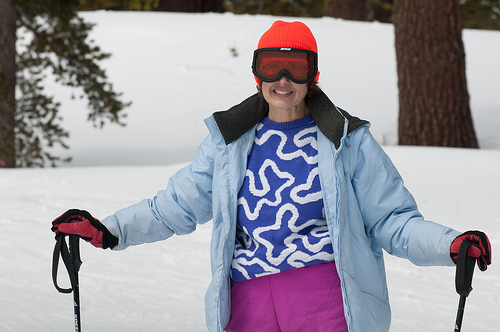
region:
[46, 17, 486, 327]
woman standing in snow with red hat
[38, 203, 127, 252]
pink and black glove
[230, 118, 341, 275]
purple and white shirt with abstract design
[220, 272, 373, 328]
top of a pair of pink pants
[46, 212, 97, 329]
gloved hand holding ski pole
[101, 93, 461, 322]
light blue snow jacket with black collar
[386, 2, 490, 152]
brown tree trunk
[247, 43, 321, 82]
black goggles with tinted lens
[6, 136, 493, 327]
white snow on ground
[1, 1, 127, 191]
green leaf tree with brown tree trunk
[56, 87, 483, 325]
this is a jacket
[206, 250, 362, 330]
these are purple pants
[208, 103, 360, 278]
this is a blue sweater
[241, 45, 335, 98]
these are eye goggles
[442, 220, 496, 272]
this is the left hand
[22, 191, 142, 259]
this is the right hand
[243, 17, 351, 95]
this is a hat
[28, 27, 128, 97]
these are green leaves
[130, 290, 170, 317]
this is the snow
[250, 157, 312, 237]
this is white pattern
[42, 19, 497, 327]
a female skier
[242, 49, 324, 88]
black protective eye wear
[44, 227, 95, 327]
a black ski pole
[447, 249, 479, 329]
a black ski pole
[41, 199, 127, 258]
a black and red ski glove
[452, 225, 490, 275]
a black and red ski glove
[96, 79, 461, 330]
a light blue winter coat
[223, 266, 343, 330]
a pair of bright purple pants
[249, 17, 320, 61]
a bright orange stocking cap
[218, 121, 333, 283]
a blue and white patterned sweater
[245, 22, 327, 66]
a red hat on a woman's head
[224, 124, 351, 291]
a blue and white sweater on a woman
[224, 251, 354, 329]
pink pants on a woman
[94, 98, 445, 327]
a light blue coat on a woman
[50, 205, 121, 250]
a pink and black glove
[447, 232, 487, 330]
a ski pole in a hand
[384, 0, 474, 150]
a brown tree trunk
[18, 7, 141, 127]
a leaf covered limb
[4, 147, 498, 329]
a snowy white slope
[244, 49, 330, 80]
ski goggles on a woman's face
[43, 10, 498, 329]
woman standing on a ski slope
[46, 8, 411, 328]
woman wearing a red ski hat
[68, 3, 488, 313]
woman wearing a blue and white sweater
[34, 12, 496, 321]
woman wearing a two ski gloves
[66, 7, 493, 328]
woman wearing hot pink ski pants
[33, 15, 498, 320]
woman wearing black and red ski goggles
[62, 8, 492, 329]
woman wearing a light blue ski jacket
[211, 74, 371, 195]
black collar on a blue ski jacket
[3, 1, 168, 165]
tree in the background of a ski slope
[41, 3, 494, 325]
woman holding two ski poles